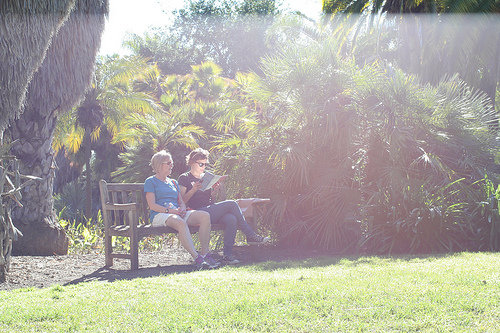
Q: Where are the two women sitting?
A: On the bench.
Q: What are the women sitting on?
A: A bench.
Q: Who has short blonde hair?
A: The woman on the bench.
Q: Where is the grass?
A: On the ground.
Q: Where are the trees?
A: Behind the women.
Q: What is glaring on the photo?
A: Sunlight.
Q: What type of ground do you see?
A: Grass.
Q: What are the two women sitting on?
A: A bench.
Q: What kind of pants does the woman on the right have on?
A: Jeans.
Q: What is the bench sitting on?
A: Dirt.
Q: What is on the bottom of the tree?
A: Bark.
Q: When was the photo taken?
A: During daylight.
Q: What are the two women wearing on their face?
A: Sunglasses.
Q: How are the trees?
A: Leafy.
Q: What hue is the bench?
A: Brown.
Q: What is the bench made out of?
A: Wood.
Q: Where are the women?
A: In a park.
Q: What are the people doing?
A: Talking.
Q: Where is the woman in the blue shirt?
A: On the bench.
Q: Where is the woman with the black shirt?
A: On the bench.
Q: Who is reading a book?
A: The woman on the bench.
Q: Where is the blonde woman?
A: On the bench.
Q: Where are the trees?
A: Behind the women.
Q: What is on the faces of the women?
A: Sunglasses.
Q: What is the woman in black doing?
A: Reading.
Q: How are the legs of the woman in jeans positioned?
A: Crossed.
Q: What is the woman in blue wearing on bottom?
A: Shorts.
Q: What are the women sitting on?
A: A bench.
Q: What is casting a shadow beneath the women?
A: The bench.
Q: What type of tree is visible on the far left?
A: A palm tree.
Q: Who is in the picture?
A: Two women.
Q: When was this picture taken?
A: Daytime.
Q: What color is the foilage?
A: Green.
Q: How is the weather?
A: Sunny.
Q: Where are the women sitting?
A: On a bench.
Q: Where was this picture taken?
A: A park.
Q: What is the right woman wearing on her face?
A: Sunglasses.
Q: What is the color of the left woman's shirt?
A: Blue.